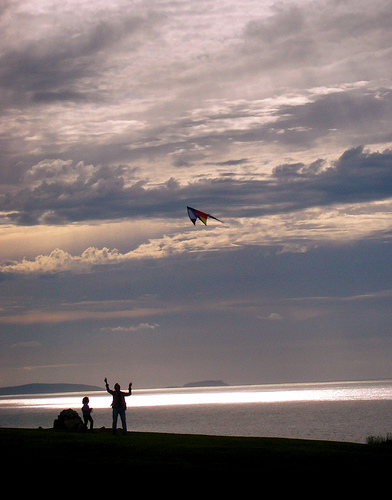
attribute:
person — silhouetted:
[103, 376, 134, 435]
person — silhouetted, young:
[81, 394, 94, 430]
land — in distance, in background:
[2, 379, 107, 396]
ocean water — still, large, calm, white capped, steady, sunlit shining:
[1, 379, 391, 444]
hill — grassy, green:
[2, 423, 389, 499]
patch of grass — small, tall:
[365, 434, 391, 445]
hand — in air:
[127, 382, 136, 388]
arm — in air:
[105, 379, 115, 395]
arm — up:
[122, 382, 135, 396]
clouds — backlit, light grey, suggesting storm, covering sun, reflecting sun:
[2, 2, 391, 384]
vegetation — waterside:
[54, 406, 87, 430]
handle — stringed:
[104, 372, 110, 381]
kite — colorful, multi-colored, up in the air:
[181, 206, 221, 231]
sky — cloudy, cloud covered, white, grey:
[95, 81, 207, 117]